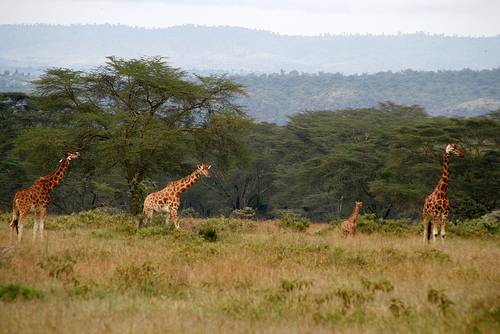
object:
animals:
[420, 142, 463, 250]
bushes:
[274, 205, 312, 233]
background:
[0, 0, 499, 333]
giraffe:
[7, 151, 82, 243]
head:
[56, 148, 83, 164]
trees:
[0, 52, 278, 214]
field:
[0, 213, 499, 334]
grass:
[0, 207, 499, 333]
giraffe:
[338, 198, 361, 239]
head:
[195, 161, 213, 180]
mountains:
[0, 61, 498, 125]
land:
[0, 208, 499, 333]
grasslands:
[0, 207, 499, 333]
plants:
[434, 289, 456, 317]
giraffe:
[137, 161, 212, 230]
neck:
[174, 171, 200, 192]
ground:
[0, 210, 499, 334]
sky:
[0, 0, 499, 40]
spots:
[164, 191, 170, 199]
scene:
[0, 0, 499, 334]